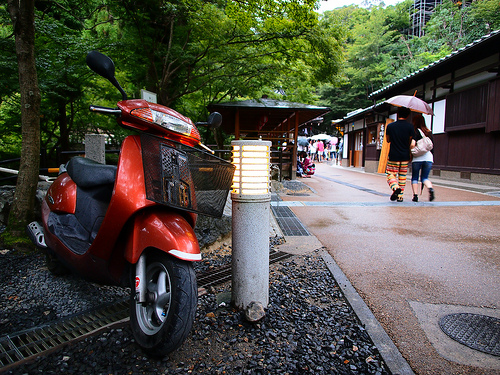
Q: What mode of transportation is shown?
A: Scooter.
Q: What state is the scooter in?
A: Parked.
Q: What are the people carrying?
A: Umbrella.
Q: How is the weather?
A: Rainy.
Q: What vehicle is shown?
A: Motorcycle.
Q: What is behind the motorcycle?
A: Tree.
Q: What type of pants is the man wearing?
A: Stripes.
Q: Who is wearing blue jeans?
A: Woman under umbrella.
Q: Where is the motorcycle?
A: Concrete.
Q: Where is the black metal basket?
A: On the scooter.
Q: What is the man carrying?
A: An umbrella.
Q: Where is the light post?
A: On the street side.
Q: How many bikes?
A: 1.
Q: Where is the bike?
A: Next to the light.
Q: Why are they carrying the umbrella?
A: Raining.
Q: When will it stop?
A: Soon.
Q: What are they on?
A: Sidewalk.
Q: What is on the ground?
A: Water.